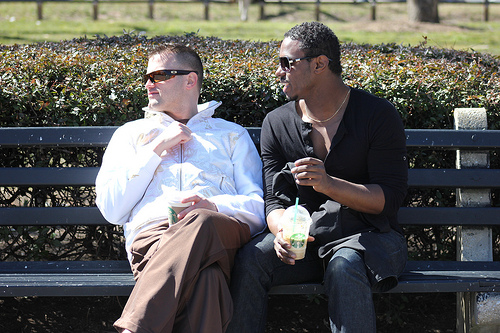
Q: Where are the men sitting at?
A: The bench.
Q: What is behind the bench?
A: A hedge.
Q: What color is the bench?
A: Black.